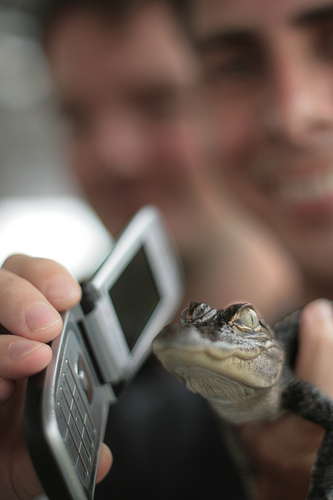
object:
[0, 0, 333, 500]
man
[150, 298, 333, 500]
snake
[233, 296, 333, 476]
hand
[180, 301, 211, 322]
eyes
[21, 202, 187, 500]
cellphone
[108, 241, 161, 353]
screen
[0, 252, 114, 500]
hand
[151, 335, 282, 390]
mouth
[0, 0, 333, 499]
picture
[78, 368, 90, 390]
controls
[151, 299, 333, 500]
alligator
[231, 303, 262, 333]
eye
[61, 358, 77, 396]
buttons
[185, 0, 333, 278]
faces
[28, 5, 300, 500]
men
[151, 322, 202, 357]
snout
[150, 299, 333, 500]
dinosaur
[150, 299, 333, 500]
lizard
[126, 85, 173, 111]
eye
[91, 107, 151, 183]
nose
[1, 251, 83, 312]
finger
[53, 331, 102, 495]
keypad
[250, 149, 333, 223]
smile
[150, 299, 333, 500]
frog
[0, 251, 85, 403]
fingers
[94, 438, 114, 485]
thumb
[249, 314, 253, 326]
slit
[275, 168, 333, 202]
teeth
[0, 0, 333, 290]
background